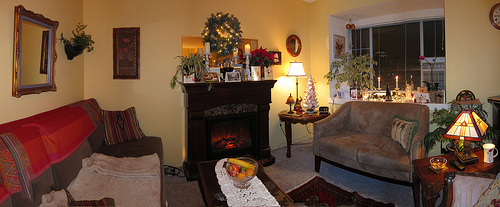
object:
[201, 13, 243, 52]
wreath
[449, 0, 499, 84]
wall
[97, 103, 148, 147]
pillow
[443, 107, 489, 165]
lamp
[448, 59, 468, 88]
ground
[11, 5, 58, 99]
mirror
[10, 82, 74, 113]
wall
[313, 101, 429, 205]
couch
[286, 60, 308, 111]
lamp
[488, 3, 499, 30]
clock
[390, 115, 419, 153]
pillow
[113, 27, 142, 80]
picture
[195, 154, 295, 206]
table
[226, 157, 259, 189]
bowl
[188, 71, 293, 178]
fireplace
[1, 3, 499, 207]
living room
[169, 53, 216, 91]
pot plant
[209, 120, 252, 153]
fire place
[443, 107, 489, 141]
glass lampshade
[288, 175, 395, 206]
rug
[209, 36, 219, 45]
reef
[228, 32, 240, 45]
lights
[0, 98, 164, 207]
couch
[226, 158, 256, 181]
fruit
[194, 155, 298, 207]
coffee table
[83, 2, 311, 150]
wall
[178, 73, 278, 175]
fireplace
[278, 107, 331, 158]
table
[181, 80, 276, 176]
fireplace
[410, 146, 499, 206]
end table